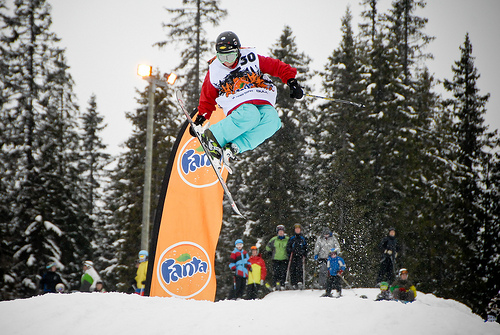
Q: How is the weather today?
A: It is cloudy.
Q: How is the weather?
A: It is cloudy.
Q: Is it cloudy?
A: Yes, it is cloudy.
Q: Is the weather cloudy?
A: Yes, it is cloudy.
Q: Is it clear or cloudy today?
A: It is cloudy.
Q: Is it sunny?
A: No, it is cloudy.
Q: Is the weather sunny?
A: No, it is cloudy.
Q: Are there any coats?
A: Yes, there is a coat.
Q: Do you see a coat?
A: Yes, there is a coat.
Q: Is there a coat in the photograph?
A: Yes, there is a coat.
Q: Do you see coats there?
A: Yes, there is a coat.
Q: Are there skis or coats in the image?
A: Yes, there is a coat.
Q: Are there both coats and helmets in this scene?
A: Yes, there are both a coat and a helmet.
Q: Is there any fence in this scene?
A: No, there are no fences.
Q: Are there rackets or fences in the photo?
A: No, there are no fences or rackets.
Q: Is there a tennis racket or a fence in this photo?
A: No, there are no fences or rackets.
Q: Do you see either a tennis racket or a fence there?
A: No, there are no fences or rackets.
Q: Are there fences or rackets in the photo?
A: No, there are no fences or rackets.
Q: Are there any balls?
A: No, there are no balls.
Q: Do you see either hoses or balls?
A: No, there are no balls or hoses.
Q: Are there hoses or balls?
A: No, there are no balls or hoses.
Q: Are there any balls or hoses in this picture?
A: No, there are no balls or hoses.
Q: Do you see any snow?
A: Yes, there is snow.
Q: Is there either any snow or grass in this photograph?
A: Yes, there is snow.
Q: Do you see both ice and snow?
A: No, there is snow but no ice.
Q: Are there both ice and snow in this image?
A: No, there is snow but no ice.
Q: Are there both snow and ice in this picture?
A: No, there is snow but no ice.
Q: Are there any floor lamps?
A: No, there are no floor lamps.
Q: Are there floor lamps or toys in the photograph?
A: No, there are no floor lamps or toys.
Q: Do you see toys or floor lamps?
A: No, there are no floor lamps or toys.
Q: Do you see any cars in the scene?
A: No, there are no cars.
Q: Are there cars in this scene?
A: No, there are no cars.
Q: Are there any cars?
A: No, there are no cars.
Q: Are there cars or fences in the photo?
A: No, there are no cars or fences.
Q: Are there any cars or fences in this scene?
A: No, there are no cars or fences.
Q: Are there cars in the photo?
A: No, there are no cars.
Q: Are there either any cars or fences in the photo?
A: No, there are no cars or fences.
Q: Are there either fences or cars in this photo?
A: No, there are no cars or fences.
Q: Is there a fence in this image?
A: No, there are no fences.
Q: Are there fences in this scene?
A: No, there are no fences.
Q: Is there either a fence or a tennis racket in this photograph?
A: No, there are no fences or rackets.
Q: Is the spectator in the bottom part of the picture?
A: Yes, the spectator is in the bottom of the image.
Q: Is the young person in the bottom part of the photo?
A: Yes, the spectator is in the bottom of the image.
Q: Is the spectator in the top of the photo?
A: No, the spectator is in the bottom of the image.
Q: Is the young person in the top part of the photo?
A: No, the spectator is in the bottom of the image.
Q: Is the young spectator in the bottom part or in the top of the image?
A: The spectator is in the bottom of the image.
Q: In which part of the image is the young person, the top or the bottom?
A: The spectator is in the bottom of the image.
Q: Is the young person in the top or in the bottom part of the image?
A: The spectator is in the bottom of the image.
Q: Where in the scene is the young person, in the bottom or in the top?
A: The spectator is in the bottom of the image.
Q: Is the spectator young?
A: Yes, the spectator is young.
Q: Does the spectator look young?
A: Yes, the spectator is young.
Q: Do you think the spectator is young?
A: Yes, the spectator is young.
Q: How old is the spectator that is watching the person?
A: The spectator is young.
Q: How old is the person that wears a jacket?
A: The spectator is young.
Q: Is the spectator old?
A: No, the spectator is young.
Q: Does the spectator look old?
A: No, the spectator is young.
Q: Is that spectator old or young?
A: The spectator is young.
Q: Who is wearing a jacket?
A: The spectator is wearing a jacket.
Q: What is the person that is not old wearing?
A: The spectator is wearing a jacket.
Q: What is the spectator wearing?
A: The spectator is wearing a jacket.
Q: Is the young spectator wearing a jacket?
A: Yes, the spectator is wearing a jacket.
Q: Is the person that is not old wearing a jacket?
A: Yes, the spectator is wearing a jacket.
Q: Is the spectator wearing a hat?
A: No, the spectator is wearing a jacket.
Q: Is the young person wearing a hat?
A: No, the spectator is wearing a jacket.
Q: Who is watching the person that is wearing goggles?
A: The spectator is watching the person.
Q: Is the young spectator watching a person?
A: Yes, the spectator is watching a person.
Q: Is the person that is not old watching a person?
A: Yes, the spectator is watching a person.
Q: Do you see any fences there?
A: No, there are no fences.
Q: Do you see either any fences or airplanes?
A: No, there are no fences or airplanes.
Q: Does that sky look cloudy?
A: Yes, the sky is cloudy.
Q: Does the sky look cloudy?
A: Yes, the sky is cloudy.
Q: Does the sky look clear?
A: No, the sky is cloudy.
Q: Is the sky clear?
A: No, the sky is cloudy.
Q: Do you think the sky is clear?
A: No, the sky is cloudy.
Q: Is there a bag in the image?
A: No, there are no bags.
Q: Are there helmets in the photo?
A: Yes, there is a helmet.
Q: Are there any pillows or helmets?
A: Yes, there is a helmet.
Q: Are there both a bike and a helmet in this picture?
A: No, there is a helmet but no bikes.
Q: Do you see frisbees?
A: No, there are no frisbees.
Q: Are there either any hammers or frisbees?
A: No, there are no frisbees or hammers.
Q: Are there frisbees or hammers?
A: No, there are no frisbees or hammers.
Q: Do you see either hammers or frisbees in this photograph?
A: No, there are no frisbees or hammers.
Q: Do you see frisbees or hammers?
A: No, there are no frisbees or hammers.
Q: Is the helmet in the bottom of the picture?
A: No, the helmet is in the top of the image.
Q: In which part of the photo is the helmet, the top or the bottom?
A: The helmet is in the top of the image.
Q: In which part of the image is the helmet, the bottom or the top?
A: The helmet is in the top of the image.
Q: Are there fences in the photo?
A: No, there are no fences.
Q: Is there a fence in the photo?
A: No, there are no fences.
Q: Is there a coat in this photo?
A: Yes, there is a coat.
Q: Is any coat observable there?
A: Yes, there is a coat.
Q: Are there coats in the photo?
A: Yes, there is a coat.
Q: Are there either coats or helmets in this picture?
A: Yes, there is a coat.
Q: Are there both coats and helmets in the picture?
A: Yes, there are both a coat and a helmet.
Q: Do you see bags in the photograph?
A: No, there are no bags.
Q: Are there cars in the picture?
A: No, there are no cars.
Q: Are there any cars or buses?
A: No, there are no cars or buses.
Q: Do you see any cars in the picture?
A: No, there are no cars.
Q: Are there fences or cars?
A: No, there are no cars or fences.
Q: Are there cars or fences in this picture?
A: No, there are no cars or fences.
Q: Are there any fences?
A: No, there are no fences.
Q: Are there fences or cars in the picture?
A: No, there are no fences or cars.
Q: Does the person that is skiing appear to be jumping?
A: Yes, the person is jumping.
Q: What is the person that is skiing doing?
A: The person is jumping.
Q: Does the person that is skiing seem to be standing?
A: No, the person is jumping.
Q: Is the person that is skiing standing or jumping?
A: The person is jumping.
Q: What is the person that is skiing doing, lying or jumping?
A: The person is jumping.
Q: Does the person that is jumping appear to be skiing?
A: Yes, the person is skiing.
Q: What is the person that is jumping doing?
A: The person is skiing.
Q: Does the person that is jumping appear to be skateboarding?
A: No, the person is skiing.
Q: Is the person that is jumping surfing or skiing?
A: The person is skiing.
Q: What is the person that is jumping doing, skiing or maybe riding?
A: The person is skiing.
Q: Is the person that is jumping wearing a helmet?
A: Yes, the person is wearing a helmet.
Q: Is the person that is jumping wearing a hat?
A: No, the person is wearing a helmet.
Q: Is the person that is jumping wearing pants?
A: Yes, the person is wearing pants.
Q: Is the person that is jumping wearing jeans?
A: No, the person is wearing pants.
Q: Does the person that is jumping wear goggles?
A: Yes, the person wears goggles.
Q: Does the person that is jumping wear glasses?
A: No, the person wears goggles.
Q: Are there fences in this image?
A: No, there are no fences.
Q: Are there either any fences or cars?
A: No, there are no fences or cars.